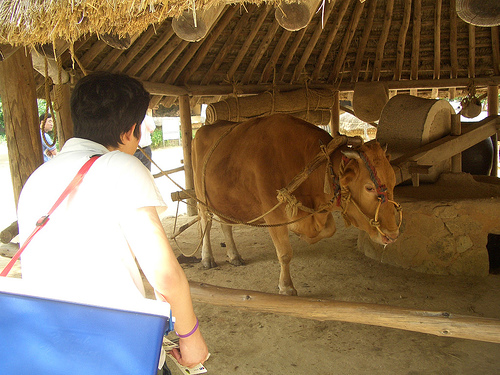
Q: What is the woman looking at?
A: The cow.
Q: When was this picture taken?
A: Daytime.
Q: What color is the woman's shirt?
A: White.